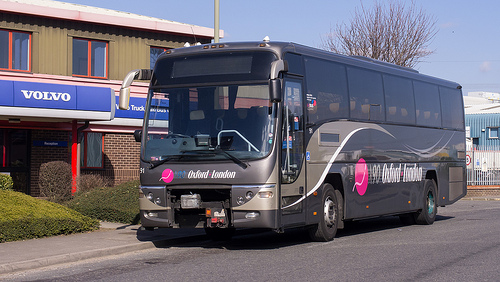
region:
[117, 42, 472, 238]
shiny grey and silver bus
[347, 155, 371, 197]
pink and white logo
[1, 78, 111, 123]
blue and white volvo sign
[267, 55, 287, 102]
silver and black sideview mirror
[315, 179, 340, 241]
black tire with silver rim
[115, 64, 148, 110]
silver side view mirror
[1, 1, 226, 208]
aluminum and brick building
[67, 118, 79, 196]
metal red pole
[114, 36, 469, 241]
large mass transit bus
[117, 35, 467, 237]
shiny bus with pink logo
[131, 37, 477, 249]
the bus is gray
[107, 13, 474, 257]
the bus is gray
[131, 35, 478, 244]
the bus is gray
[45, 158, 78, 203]
a green bush in front of building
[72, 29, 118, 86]
a window on the building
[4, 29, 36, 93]
a window on the building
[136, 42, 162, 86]
a window on the building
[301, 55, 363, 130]
a window on the bus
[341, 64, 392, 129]
a window on the bus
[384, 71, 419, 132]
a window on the bus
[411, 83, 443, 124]
a window on the bus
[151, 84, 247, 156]
a window on the bus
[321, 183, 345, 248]
a tire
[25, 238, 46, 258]
the sidewalk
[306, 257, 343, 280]
the street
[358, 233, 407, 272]
the street is grey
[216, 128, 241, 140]
a grey railing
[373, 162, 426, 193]
writing on the bus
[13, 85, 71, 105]
logo on the building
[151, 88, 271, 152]
front windshield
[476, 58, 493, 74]
cloud in the sky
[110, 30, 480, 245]
big bus on the road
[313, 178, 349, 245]
wheel of a big bus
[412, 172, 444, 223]
wheel of a big bus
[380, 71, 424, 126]
window of a big bus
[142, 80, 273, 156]
window of a big bus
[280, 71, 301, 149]
window of a big bus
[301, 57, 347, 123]
window of a big bus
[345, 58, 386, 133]
window of a big bus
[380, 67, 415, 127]
window of a big bus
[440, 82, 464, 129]
window of a big bus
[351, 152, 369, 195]
Round pink logo on the gray bus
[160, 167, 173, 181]
Small round pink logo on the gray bus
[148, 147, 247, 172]
Black windshield wipers on the gray bus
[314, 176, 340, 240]
front black tire on the gray bus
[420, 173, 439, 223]
back black tire on the gray bus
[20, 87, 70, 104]
White logo on the blue store sign